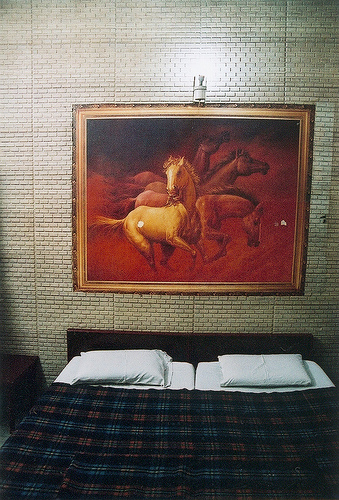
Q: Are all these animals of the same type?
A: Yes, all the animals are horses.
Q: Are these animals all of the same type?
A: Yes, all the animals are horses.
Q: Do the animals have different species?
A: No, all the animals are horses.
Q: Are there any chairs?
A: No, there are no chairs.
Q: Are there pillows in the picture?
A: Yes, there is a pillow.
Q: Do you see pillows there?
A: Yes, there is a pillow.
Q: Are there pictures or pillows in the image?
A: Yes, there is a pillow.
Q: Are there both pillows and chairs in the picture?
A: No, there is a pillow but no chairs.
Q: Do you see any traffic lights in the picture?
A: No, there are no traffic lights.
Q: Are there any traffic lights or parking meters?
A: No, there are no traffic lights or parking meters.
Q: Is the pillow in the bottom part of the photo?
A: Yes, the pillow is in the bottom of the image.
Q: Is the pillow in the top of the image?
A: No, the pillow is in the bottom of the image.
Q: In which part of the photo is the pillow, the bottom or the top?
A: The pillow is in the bottom of the image.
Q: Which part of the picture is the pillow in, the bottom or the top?
A: The pillow is in the bottom of the image.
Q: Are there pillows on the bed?
A: Yes, there is a pillow on the bed.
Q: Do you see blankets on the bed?
A: No, there is a pillow on the bed.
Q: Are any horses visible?
A: Yes, there is a horse.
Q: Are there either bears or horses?
A: Yes, there is a horse.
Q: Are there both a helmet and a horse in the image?
A: No, there is a horse but no helmets.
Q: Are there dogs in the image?
A: No, there are no dogs.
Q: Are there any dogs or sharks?
A: No, there are no dogs or sharks.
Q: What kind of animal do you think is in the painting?
A: The animal is a horse.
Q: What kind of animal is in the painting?
A: The animal is a horse.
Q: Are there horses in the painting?
A: Yes, there is a horse in the painting.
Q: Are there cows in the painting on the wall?
A: No, there is a horse in the painting.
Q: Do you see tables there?
A: Yes, there is a table.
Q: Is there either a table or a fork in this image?
A: Yes, there is a table.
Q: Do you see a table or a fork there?
A: Yes, there is a table.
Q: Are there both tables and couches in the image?
A: No, there is a table but no couches.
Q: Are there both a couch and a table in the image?
A: No, there is a table but no couches.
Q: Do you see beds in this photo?
A: Yes, there is a bed.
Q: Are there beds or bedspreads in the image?
A: Yes, there is a bed.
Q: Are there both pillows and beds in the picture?
A: Yes, there are both a bed and pillows.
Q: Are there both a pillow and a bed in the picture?
A: Yes, there are both a bed and a pillow.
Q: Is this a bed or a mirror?
A: This is a bed.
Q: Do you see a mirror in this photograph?
A: No, there are no mirrors.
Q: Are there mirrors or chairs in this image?
A: No, there are no mirrors or chairs.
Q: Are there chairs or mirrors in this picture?
A: No, there are no mirrors or chairs.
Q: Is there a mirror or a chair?
A: No, there are no mirrors or chairs.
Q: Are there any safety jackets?
A: No, there are no safety jackets.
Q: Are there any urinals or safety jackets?
A: No, there are no safety jackets or urinals.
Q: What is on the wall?
A: The painting is on the wall.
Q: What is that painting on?
A: The painting is on the wall.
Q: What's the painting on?
A: The painting is on the wall.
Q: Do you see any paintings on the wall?
A: Yes, there is a painting on the wall.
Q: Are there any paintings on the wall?
A: Yes, there is a painting on the wall.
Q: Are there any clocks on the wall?
A: No, there is a painting on the wall.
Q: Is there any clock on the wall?
A: No, there is a painting on the wall.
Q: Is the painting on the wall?
A: Yes, the painting is on the wall.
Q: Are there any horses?
A: Yes, there is a horse.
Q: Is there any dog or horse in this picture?
A: Yes, there is a horse.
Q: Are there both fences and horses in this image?
A: No, there is a horse but no fences.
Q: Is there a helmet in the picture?
A: No, there are no helmets.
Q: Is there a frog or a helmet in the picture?
A: No, there are no helmets or frogs.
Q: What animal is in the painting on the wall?
A: The horse is in the painting.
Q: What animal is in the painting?
A: The horse is in the painting.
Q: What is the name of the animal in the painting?
A: The animal is a horse.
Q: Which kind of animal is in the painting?
A: The animal is a horse.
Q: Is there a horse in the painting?
A: Yes, there is a horse in the painting.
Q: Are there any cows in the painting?
A: No, there is a horse in the painting.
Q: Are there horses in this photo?
A: Yes, there is a horse.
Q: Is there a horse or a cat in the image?
A: Yes, there is a horse.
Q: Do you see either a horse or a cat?
A: Yes, there is a horse.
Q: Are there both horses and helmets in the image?
A: No, there is a horse but no helmets.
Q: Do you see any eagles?
A: No, there are no eagles.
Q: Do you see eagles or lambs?
A: No, there are no eagles or lambs.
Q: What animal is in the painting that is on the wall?
A: The horse is in the painting.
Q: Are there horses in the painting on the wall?
A: Yes, there is a horse in the painting.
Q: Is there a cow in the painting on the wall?
A: No, there is a horse in the painting.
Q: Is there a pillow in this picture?
A: Yes, there is a pillow.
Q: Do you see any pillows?
A: Yes, there is a pillow.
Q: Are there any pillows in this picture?
A: Yes, there is a pillow.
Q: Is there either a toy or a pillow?
A: Yes, there is a pillow.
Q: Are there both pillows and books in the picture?
A: No, there is a pillow but no books.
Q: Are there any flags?
A: No, there are no flags.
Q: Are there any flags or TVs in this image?
A: No, there are no flags or tvs.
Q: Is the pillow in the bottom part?
A: Yes, the pillow is in the bottom of the image.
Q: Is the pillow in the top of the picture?
A: No, the pillow is in the bottom of the image.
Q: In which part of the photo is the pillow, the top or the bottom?
A: The pillow is in the bottom of the image.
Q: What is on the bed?
A: The pillow is on the bed.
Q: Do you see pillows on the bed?
A: Yes, there is a pillow on the bed.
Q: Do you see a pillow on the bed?
A: Yes, there is a pillow on the bed.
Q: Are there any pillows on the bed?
A: Yes, there is a pillow on the bed.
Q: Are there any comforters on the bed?
A: No, there is a pillow on the bed.